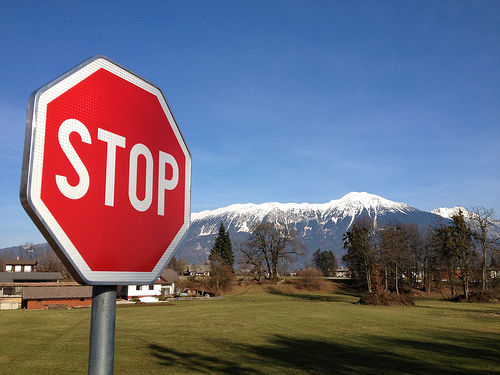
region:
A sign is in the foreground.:
[13, 44, 208, 374]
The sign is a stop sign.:
[5, 49, 224, 294]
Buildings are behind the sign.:
[0, 250, 195, 322]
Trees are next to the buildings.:
[177, 206, 488, 308]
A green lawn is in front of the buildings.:
[1, 293, 480, 373]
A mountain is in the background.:
[157, 183, 479, 286]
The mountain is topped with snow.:
[188, 177, 468, 240]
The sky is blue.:
[0, 1, 497, 131]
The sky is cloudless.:
[1, 0, 498, 154]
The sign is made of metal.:
[12, 40, 229, 374]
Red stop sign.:
[15, 46, 207, 301]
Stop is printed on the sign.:
[48, 106, 187, 229]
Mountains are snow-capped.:
[192, 181, 469, 278]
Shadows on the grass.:
[137, 306, 379, 373]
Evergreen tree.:
[207, 218, 244, 303]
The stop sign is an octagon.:
[16, 43, 221, 309]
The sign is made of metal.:
[13, 49, 201, 372]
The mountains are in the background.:
[170, 176, 495, 373]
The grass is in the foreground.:
[190, 183, 496, 353]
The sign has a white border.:
[12, 48, 217, 302]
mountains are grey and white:
[138, 174, 497, 292]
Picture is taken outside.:
[10, 16, 472, 355]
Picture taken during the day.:
[5, 40, 480, 362]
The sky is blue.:
[6, 48, 490, 245]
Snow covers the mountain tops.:
[210, 200, 467, 232]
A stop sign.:
[25, 61, 249, 285]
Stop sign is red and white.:
[29, 42, 217, 328]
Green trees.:
[210, 212, 495, 321]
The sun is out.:
[209, 51, 494, 318]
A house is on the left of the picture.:
[7, 229, 191, 356]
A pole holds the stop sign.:
[65, 250, 124, 370]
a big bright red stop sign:
[21, 45, 226, 340]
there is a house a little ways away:
[121, 274, 202, 303]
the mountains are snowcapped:
[209, 191, 427, 252]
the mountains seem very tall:
[227, 191, 485, 331]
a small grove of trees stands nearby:
[339, 188, 485, 344]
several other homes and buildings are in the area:
[2, 251, 87, 328]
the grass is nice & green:
[166, 314, 354, 361]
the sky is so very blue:
[216, 30, 388, 160]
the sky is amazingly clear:
[193, 34, 453, 146]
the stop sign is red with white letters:
[37, 57, 205, 315]